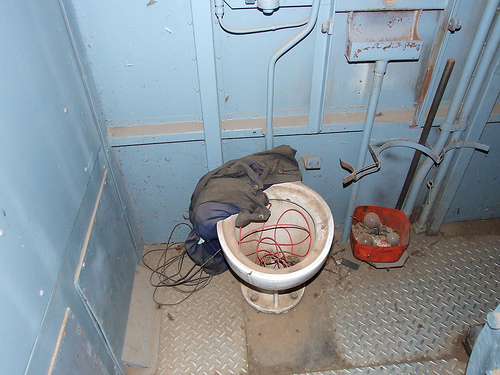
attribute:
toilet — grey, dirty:
[208, 172, 359, 309]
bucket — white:
[216, 180, 333, 312]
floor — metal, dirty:
[172, 287, 283, 367]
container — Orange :
[349, 204, 411, 262]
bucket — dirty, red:
[349, 206, 376, 258]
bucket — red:
[352, 201, 416, 253]